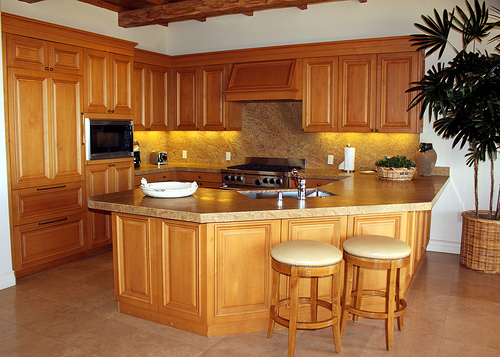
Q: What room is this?
A: A kitchen.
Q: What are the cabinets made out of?
A: Wood.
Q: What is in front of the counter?
A: Chairs.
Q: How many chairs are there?
A: Two.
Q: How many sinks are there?
A: One.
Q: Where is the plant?
A: On the right.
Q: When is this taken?
A: Daytime.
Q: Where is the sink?
A: On the center island.